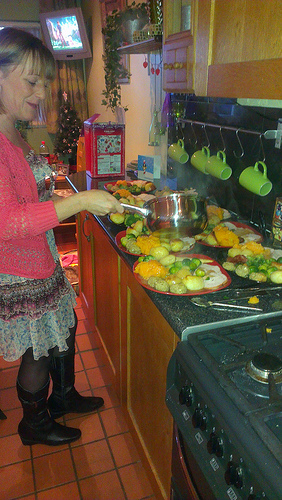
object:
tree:
[53, 88, 85, 162]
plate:
[106, 179, 156, 197]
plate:
[115, 224, 197, 254]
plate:
[226, 242, 280, 280]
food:
[113, 180, 143, 192]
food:
[208, 205, 222, 221]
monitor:
[38, 6, 91, 67]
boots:
[15, 382, 81, 446]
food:
[132, 247, 231, 294]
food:
[220, 243, 281, 282]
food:
[202, 222, 260, 247]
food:
[109, 203, 146, 228]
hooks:
[170, 115, 266, 162]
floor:
[0, 325, 93, 497]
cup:
[238, 160, 272, 196]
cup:
[206, 148, 232, 183]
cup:
[190, 145, 208, 174]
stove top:
[246, 335, 281, 385]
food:
[115, 217, 197, 257]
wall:
[166, 90, 281, 248]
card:
[137, 152, 161, 183]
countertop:
[64, 166, 281, 338]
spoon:
[189, 292, 271, 319]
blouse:
[0, 128, 59, 279]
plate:
[195, 219, 262, 247]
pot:
[120, 193, 207, 239]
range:
[231, 339, 280, 400]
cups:
[167, 138, 191, 166]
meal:
[108, 176, 279, 298]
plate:
[134, 253, 230, 295]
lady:
[1, 25, 125, 447]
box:
[83, 114, 126, 180]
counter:
[65, 162, 280, 498]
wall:
[1, 2, 156, 174]